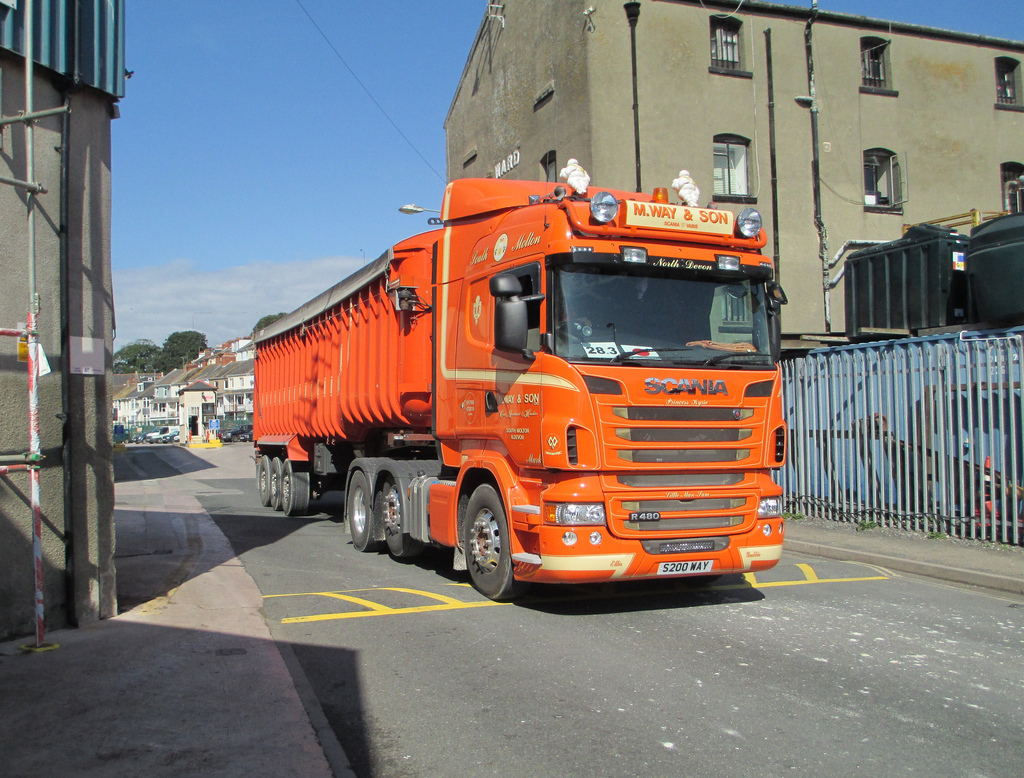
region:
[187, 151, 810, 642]
orange truck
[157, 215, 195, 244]
white clouds in the blue sky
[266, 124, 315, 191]
white clouds in the blue sky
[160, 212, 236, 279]
white clouds in the blue sky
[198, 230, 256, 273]
white clouds in the blue sky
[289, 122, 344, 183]
white clouds in the blue sky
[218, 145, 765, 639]
large orange truck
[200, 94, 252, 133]
white clouds in the blue sky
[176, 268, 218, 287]
white clouds in the blue sky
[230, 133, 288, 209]
white clouds in the blue sky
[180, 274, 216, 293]
white clouds in the blue sky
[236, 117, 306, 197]
white clouds in the blue sky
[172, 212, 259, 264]
white clouds in blue sky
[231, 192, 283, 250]
white clouds in the blue sky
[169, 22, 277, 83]
white clouds in the blue sky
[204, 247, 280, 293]
white clouds in the blue sky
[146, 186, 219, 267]
white clouds in the blue sky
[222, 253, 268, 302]
white clouds in the blue sky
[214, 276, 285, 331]
white clouds in blue sky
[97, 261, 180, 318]
white clouds in blue sky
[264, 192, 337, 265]
white clouds in blue sky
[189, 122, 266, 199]
white clouds in blue sky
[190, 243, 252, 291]
white clouds in blue sky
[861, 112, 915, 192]
a window on the building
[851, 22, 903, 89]
a window on the building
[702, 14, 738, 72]
glass window on the building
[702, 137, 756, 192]
glass window on the building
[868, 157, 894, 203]
glass window on the building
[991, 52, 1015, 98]
glass window on the building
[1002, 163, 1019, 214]
glass window on the building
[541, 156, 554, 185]
glass window on the building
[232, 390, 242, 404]
glass window on the building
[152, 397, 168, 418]
glass window on the building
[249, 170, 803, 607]
Large orange dump truck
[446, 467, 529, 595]
Right front wheel of truck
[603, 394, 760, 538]
Front facing grill of truck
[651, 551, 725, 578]
License plate of orange truck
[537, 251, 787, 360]
The windshield of orange truck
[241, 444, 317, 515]
Three back wheels of truck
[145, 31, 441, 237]
Blue sky with no clouds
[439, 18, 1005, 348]
A large gray building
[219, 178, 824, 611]
Orange truck stopped on the street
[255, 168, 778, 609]
large orange truck on the road